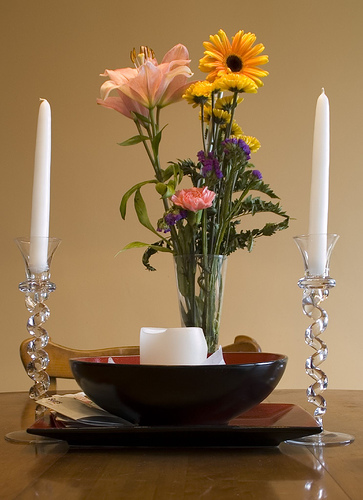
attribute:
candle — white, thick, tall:
[307, 88, 328, 275]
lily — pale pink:
[96, 40, 191, 112]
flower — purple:
[222, 134, 251, 162]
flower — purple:
[252, 168, 262, 182]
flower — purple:
[201, 160, 222, 183]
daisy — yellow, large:
[199, 28, 268, 90]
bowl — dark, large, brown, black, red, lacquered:
[68, 352, 288, 425]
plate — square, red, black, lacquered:
[25, 401, 320, 450]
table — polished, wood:
[1, 390, 361, 499]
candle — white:
[29, 97, 51, 274]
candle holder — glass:
[282, 231, 354, 448]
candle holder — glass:
[5, 235, 65, 444]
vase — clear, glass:
[171, 256, 226, 350]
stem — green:
[140, 111, 180, 254]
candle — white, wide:
[138, 323, 208, 364]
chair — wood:
[19, 334, 261, 392]